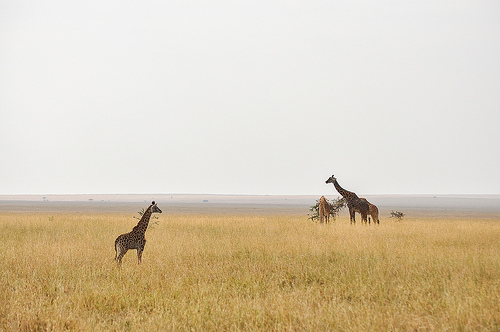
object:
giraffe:
[322, 172, 371, 224]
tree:
[310, 191, 345, 224]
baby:
[110, 200, 163, 269]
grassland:
[1, 195, 499, 331]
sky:
[0, 0, 499, 196]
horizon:
[0, 191, 499, 211]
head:
[324, 173, 338, 184]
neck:
[331, 180, 348, 199]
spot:
[340, 189, 344, 194]